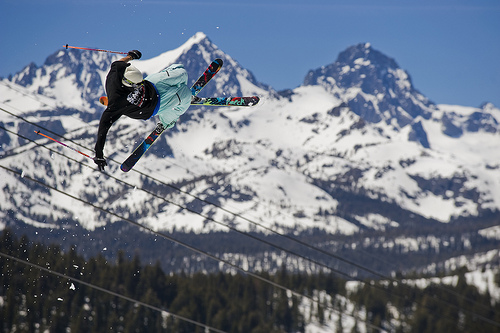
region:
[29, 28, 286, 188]
person skiing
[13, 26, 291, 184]
person in the air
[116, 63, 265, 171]
two long and thin skis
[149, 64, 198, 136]
light blue ski pants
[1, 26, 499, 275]
mountain range covered in snow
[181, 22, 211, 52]
pointed mountaintop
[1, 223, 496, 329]
pine trees growing out of the white snow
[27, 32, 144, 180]
arms outstretched for balance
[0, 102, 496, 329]
black wires pulled tightly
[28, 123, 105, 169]
skinny orange stick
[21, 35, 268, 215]
A person skiing.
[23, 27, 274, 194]
A skier making a jump.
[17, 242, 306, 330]
Trees are in the background.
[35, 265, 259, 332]
The trees are green.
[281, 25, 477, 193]
Mountains are in the background.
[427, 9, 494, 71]
The sky is blue.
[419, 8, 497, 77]
The sky is clear.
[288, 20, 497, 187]
Snow is on the mountains.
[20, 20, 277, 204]
The person is holding ski poles.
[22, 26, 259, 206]
The person is wearing a black top.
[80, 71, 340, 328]
mountain in the background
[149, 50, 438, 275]
mountain in the background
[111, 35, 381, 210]
mountain in the background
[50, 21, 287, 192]
a skier in the air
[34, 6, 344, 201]
a person in the air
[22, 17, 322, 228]
a person on skies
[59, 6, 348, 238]
a person with skies in the air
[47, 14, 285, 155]
a person with his knees bent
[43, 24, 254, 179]
a skier with his knees bent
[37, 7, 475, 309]
a mount in the distance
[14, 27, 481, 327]
a mountain with snow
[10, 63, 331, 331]
cable cords in the sky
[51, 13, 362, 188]
a person wearing blue shorts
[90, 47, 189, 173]
The skier in the air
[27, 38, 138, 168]
The poles of the skier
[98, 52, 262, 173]
The skis of the skier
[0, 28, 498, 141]
The mountain peaks in the background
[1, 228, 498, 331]
The trees on the near ridge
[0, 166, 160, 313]
The snow in the air behind the skier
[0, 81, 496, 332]
The cables in the air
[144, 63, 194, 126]
The skiers aqua blue pants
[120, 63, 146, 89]
The white beanie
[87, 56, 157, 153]
The black sweatshirt